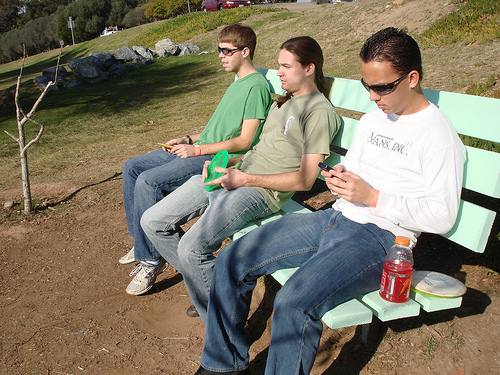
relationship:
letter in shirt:
[369, 132, 379, 143] [327, 103, 467, 243]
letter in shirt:
[371, 136, 381, 147] [327, 103, 467, 243]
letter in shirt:
[377, 138, 385, 147] [327, 103, 467, 243]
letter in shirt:
[383, 140, 391, 150] [327, 103, 467, 243]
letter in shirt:
[391, 143, 398, 150] [327, 103, 467, 243]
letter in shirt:
[391, 142, 403, 152] [327, 103, 467, 243]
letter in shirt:
[399, 146, 404, 154] [327, 103, 467, 243]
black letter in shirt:
[393, 144, 403, 152] [327, 103, 467, 243]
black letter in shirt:
[390, 140, 400, 152] [332, 99, 469, 239]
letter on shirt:
[401, 145, 407, 155] [332, 99, 469, 239]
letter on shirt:
[399, 146, 404, 154] [332, 99, 469, 239]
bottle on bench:
[377, 234, 414, 303] [231, 66, 498, 329]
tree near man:
[4, 42, 68, 217] [197, 22, 469, 374]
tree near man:
[4, 42, 68, 217] [138, 30, 342, 325]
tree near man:
[4, 42, 68, 217] [115, 20, 273, 298]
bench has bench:
[168, 62, 495, 329] [233, 68, 498, 329]